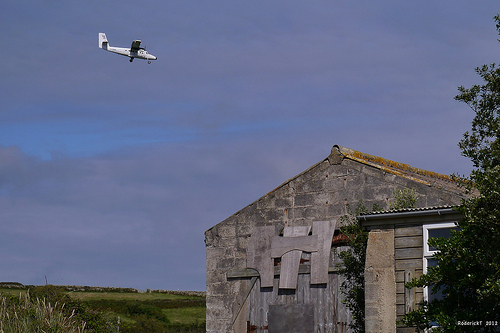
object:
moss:
[345, 150, 475, 183]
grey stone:
[205, 306, 232, 323]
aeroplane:
[98, 32, 157, 64]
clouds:
[0, 0, 97, 109]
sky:
[0, 0, 498, 290]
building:
[202, 145, 498, 333]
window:
[426, 226, 455, 252]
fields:
[0, 278, 205, 333]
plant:
[0, 291, 88, 333]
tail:
[98, 33, 110, 51]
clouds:
[101, 68, 162, 99]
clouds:
[348, 114, 431, 143]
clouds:
[66, 245, 123, 273]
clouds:
[0, 249, 74, 284]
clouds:
[0, 150, 40, 194]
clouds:
[77, 157, 113, 185]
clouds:
[126, 238, 195, 285]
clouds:
[179, 104, 234, 133]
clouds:
[223, 140, 297, 177]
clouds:
[139, 139, 190, 162]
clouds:
[160, 0, 263, 61]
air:
[127, 160, 217, 195]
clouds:
[185, 120, 220, 155]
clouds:
[96, 193, 133, 230]